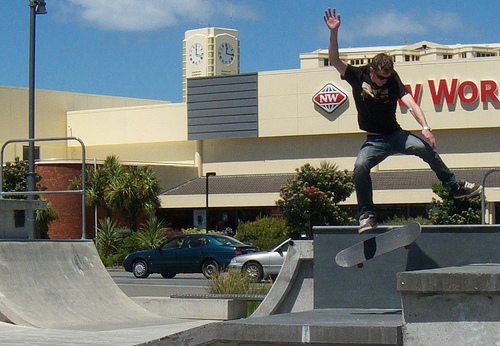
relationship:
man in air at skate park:
[321, 7, 484, 236] [0, 136, 499, 344]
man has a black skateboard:
[321, 7, 484, 236] [334, 220, 422, 269]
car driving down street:
[122, 232, 260, 280] [104, 268, 278, 298]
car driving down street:
[227, 234, 310, 285] [104, 268, 278, 298]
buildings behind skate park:
[1, 25, 499, 241] [0, 136, 499, 344]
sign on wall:
[313, 80, 346, 115] [186, 55, 499, 141]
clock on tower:
[216, 42, 237, 66] [182, 28, 241, 103]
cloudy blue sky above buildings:
[0, 0, 499, 104] [1, 25, 499, 241]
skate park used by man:
[0, 136, 499, 344] [321, 7, 484, 236]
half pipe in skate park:
[0, 240, 197, 329] [0, 136, 499, 344]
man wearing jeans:
[321, 7, 484, 236] [353, 126, 461, 219]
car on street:
[122, 232, 260, 280] [104, 268, 278, 298]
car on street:
[227, 234, 310, 285] [104, 268, 278, 298]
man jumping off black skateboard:
[321, 7, 484, 236] [334, 220, 422, 269]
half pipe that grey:
[0, 240, 197, 329] [32, 277, 64, 298]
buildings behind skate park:
[139, 58, 500, 253] [0, 136, 499, 344]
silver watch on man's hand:
[422, 124, 431, 131] [419, 125, 438, 149]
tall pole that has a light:
[24, 1, 37, 238] [36, 0, 48, 17]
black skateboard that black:
[334, 220, 422, 269] [343, 250, 359, 262]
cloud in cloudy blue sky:
[51, 0, 258, 33] [0, 0, 499, 104]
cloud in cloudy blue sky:
[316, 9, 485, 46] [0, 0, 499, 104]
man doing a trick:
[321, 7, 484, 236] [325, 6, 484, 270]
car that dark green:
[122, 232, 260, 280] [213, 245, 230, 253]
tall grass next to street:
[202, 264, 274, 320] [104, 268, 278, 298]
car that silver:
[227, 234, 310, 285] [267, 255, 281, 262]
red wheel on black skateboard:
[357, 261, 364, 270] [334, 220, 422, 269]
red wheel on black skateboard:
[403, 244, 415, 252] [334, 220, 422, 269]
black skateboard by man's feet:
[334, 220, 422, 269] [351, 179, 486, 235]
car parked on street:
[122, 232, 260, 280] [104, 268, 278, 298]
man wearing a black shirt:
[321, 7, 484, 236] [341, 61, 411, 137]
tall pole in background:
[24, 1, 37, 238] [1, 0, 499, 293]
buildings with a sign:
[139, 58, 500, 253] [313, 80, 346, 115]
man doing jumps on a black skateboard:
[321, 7, 484, 236] [334, 220, 422, 269]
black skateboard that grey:
[334, 220, 422, 269] [336, 258, 344, 266]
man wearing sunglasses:
[321, 7, 484, 236] [372, 68, 391, 81]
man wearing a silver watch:
[321, 7, 484, 236] [422, 124, 431, 131]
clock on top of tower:
[216, 42, 237, 66] [182, 28, 241, 103]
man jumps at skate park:
[321, 7, 484, 236] [0, 136, 499, 344]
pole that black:
[204, 171, 217, 231] [208, 172, 214, 176]